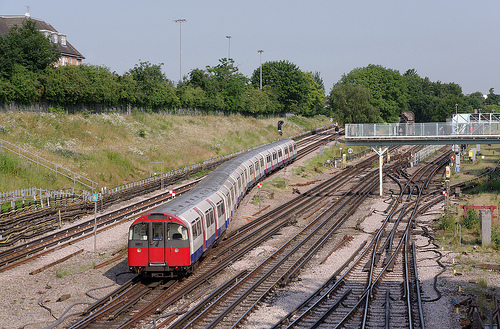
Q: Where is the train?
A: On train tracks.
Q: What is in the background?
A: Trees.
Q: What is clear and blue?
A: The sky.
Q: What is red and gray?
A: Train.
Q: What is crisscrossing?
A: Railroad tracks.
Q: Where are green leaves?
A: On many trees.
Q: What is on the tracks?
A: A train.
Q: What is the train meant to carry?
A: Passengers.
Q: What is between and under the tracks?
A: Gravel.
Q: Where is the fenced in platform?
A: Above the tracks.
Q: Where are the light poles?
A: On top of the slope.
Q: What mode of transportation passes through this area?
A: Trains.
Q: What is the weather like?
A: Clear and sunny.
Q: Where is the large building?
A: On the top of the slope on the left.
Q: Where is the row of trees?
A: On the top of the hill.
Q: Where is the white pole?
A: Holding up the platform to the right.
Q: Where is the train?
A: On the tracks.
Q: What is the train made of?
A: Metal.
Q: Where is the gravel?
A: Around the train tracks.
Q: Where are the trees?
A: Behind the hill.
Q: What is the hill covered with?
A: Grass.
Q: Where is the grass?
A: On the hill.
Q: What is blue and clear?
A: The sky.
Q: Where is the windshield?
A: The front of the train.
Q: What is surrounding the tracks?
A: Gravel.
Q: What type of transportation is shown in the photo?
A: Train.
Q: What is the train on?
A: Tracks.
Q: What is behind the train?
A: Trees.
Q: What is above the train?
A: Bridge.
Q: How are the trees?
A: Green.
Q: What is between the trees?
A: Power lines.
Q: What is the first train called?
A: Engine.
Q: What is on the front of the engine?
A: Window.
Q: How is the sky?
A: Blue.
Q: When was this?
A: Daytime.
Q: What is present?
A: A train.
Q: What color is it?
A: Grey.